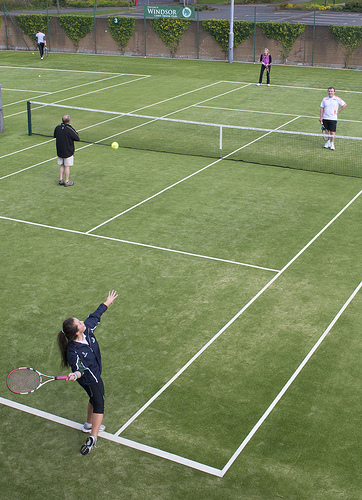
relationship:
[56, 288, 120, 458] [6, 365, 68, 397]
person has racket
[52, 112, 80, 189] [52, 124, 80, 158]
person has jacket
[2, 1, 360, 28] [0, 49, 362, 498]
parking lot above court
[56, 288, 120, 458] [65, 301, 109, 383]
person wearing jacket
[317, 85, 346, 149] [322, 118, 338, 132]
person wearing shorts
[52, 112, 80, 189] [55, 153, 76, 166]
person wearing shorts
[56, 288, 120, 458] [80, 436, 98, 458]
person wearing sneaker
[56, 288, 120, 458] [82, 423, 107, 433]
person wearing sneaker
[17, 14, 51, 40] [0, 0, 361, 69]
ivy on fence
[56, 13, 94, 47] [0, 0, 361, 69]
ivy on fence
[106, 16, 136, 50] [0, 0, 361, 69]
ivy on fence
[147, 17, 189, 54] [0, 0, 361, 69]
ivy on fence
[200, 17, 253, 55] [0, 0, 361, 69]
ivy on fence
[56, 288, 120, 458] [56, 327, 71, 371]
person has ponytail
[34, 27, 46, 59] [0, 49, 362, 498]
person on court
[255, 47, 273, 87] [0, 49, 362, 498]
person on court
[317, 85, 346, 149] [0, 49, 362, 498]
person on court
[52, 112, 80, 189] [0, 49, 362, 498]
person on court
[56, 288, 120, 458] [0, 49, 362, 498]
person on court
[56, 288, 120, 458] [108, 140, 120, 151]
person hitting ball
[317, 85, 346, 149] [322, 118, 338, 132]
person in shorts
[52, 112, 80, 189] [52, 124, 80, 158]
person in jacket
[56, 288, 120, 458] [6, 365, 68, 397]
person holding racket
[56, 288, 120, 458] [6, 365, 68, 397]
person swinging racket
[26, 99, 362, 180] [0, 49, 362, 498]
net on court